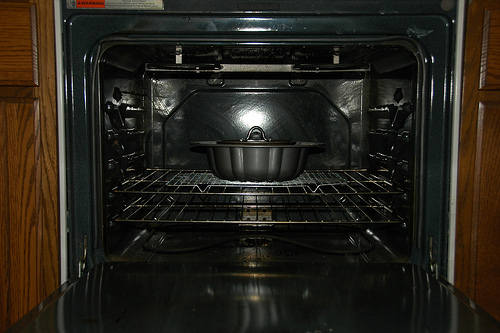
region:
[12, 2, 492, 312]
oven between wooden cabinets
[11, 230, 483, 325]
oven door pulled down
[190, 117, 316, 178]
lid above cake pan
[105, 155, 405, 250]
racks across oven width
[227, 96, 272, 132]
light reflecting off back wall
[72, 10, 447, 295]
black wall on inside of oven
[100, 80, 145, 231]
raised ridges along side of wall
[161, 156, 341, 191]
cake-cooling rack on top of oven rack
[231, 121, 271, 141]
curved handle of lid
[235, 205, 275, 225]
metal panel with two holes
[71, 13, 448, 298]
an open oven with a pot on the shelf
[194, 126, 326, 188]
a pot on in an oven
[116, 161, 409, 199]
a wire rack in an oven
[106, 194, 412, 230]
a wire rack in an oven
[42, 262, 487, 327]
the door of an oven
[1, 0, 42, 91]
a drawer of a cabinet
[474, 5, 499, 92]
a drawer of a cabinet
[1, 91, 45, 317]
a door of a cabinet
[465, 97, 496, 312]
a door of a cabinet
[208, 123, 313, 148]
the lid of a pot in an oven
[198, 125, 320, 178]
A metal pan in the oven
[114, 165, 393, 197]
A metal oven rack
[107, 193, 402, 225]
A metal oven rack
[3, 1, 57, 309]
A wooden cabinet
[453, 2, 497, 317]
A wooden cabinet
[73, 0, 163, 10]
A sticker on the oven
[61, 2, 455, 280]
A black oven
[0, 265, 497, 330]
A black oven door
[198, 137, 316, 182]
a bundt cake pan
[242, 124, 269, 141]
A metal top handle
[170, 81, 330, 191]
Baking cake pan in the stove.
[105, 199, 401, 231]
Racks in the oven.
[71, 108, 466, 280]
The oven is open.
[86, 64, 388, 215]
Oven is black inside.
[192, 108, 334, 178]
The cake pan is black.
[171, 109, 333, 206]
Cake pan is on the top rack.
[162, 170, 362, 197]
Rack underneath cake pan.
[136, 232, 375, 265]
The burner is at the bottom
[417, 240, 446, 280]
Hooks on the oven door.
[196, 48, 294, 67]
Hook on top of oven.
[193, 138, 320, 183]
A silver baking pan in the oven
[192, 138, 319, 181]
A bundt pan in the oven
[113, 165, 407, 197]
An oven rack in the oven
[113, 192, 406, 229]
An oven rack in the oven